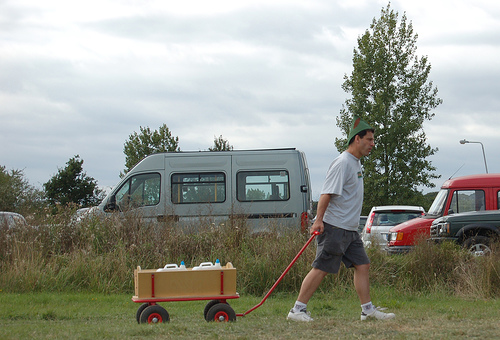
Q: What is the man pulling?
A: Wagon.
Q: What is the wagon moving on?
A: Wheels.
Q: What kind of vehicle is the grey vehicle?
A: Van.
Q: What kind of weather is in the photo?
A: Overcast.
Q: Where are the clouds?
A: In the sky.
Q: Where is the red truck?
A: In the parking lot.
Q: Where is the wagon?
A: On the ground.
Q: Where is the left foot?
A: In the left shoe.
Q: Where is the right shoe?
A: On the right foot.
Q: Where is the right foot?
A: In the right shoe.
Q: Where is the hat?
A: On the man.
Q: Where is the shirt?
A: On the man.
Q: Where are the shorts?
A: On the man.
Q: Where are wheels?
A: Under the wagon.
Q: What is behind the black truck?
A: A red van.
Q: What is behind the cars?
A: Tree.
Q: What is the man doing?
A: Pulling a wagon.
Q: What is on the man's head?
A: A green hat.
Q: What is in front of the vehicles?
A: Tall grass.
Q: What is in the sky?
A: Clouds.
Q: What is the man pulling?
A: A wagon.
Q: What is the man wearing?
A: A grey shirt and grey shorts.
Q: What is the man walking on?
A: Grass.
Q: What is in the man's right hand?
A: A wagon handle.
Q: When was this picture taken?
A: Daytime.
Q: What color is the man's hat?
A: Green.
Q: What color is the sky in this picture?
A: White.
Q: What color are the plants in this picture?
A: Green.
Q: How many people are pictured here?
A: One.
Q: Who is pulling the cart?
A: The man.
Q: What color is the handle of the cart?
A: Red.